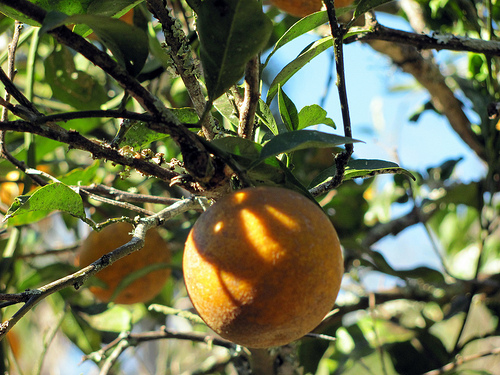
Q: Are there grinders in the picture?
A: No, there are no grinders.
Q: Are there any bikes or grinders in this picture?
A: No, there are no grinders or bikes.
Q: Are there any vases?
A: No, there are no vases.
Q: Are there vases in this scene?
A: No, there are no vases.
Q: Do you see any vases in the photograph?
A: No, there are no vases.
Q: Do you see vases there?
A: No, there are no vases.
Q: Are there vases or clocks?
A: No, there are no vases or clocks.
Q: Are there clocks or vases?
A: No, there are no vases or clocks.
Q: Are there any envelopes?
A: No, there are no envelopes.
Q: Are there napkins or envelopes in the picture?
A: No, there are no envelopes or napkins.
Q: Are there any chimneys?
A: No, there are no chimneys.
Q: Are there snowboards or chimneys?
A: No, there are no chimneys or snowboards.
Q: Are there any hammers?
A: No, there are no hammers.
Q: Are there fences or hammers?
A: No, there are no hammers or fences.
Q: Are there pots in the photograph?
A: No, there are no pots.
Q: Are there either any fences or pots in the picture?
A: No, there are no pots or fences.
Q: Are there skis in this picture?
A: No, there are no skis.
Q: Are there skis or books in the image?
A: No, there are no skis or books.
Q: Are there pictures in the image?
A: No, there are no pictures.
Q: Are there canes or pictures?
A: No, there are no pictures or canes.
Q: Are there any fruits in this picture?
A: Yes, there is a fruit.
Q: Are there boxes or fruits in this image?
A: Yes, there is a fruit.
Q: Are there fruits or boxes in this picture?
A: Yes, there is a fruit.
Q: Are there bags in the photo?
A: No, there are no bags.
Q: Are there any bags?
A: No, there are no bags.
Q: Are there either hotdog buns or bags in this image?
A: No, there are no bags or hotdog buns.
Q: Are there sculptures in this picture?
A: No, there are no sculptures.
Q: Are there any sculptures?
A: No, there are no sculptures.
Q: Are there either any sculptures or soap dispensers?
A: No, there are no sculptures or soap dispensers.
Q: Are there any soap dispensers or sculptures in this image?
A: No, there are no sculptures or soap dispensers.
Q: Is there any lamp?
A: No, there are no lamps.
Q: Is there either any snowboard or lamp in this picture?
A: No, there are no lamps or snowboards.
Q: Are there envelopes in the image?
A: No, there are no envelopes.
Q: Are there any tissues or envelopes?
A: No, there are no envelopes or tissues.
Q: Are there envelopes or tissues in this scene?
A: No, there are no envelopes or tissues.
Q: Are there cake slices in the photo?
A: No, there are no cake slices.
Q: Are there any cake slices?
A: No, there are no cake slices.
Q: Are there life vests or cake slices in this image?
A: No, there are no cake slices or life vests.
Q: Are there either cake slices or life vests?
A: No, there are no cake slices or life vests.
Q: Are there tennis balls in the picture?
A: No, there are no tennis balls.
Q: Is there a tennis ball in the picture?
A: No, there are no tennis balls.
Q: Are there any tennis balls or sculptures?
A: No, there are no tennis balls or sculptures.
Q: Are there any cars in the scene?
A: No, there are no cars.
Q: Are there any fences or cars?
A: No, there are no cars or fences.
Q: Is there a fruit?
A: Yes, there is a fruit.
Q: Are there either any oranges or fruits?
A: Yes, there is a fruit.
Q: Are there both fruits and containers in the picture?
A: No, there is a fruit but no containers.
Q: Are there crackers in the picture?
A: No, there are no crackers.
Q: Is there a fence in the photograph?
A: No, there are no fences.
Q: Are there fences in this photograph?
A: No, there are no fences.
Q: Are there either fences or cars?
A: No, there are no fences or cars.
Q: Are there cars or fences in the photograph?
A: No, there are no fences or cars.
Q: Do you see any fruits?
A: Yes, there is a fruit.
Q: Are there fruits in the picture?
A: Yes, there is a fruit.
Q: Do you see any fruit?
A: Yes, there is a fruit.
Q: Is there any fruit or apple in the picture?
A: Yes, there is a fruit.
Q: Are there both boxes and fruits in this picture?
A: No, there is a fruit but no boxes.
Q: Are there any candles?
A: No, there are no candles.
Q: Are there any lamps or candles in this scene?
A: No, there are no candles or lamps.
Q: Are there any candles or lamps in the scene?
A: No, there are no candles or lamps.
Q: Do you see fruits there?
A: Yes, there is a fruit.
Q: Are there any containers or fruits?
A: Yes, there is a fruit.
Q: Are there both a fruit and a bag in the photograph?
A: No, there is a fruit but no bags.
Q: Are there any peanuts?
A: No, there are no peanuts.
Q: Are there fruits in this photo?
A: Yes, there is a fruit.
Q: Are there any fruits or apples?
A: Yes, there is a fruit.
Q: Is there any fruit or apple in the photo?
A: Yes, there is a fruit.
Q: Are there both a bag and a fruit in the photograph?
A: No, there is a fruit but no bags.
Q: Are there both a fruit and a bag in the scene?
A: No, there is a fruit but no bags.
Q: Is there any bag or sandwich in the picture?
A: No, there are no bags or sandwiches.